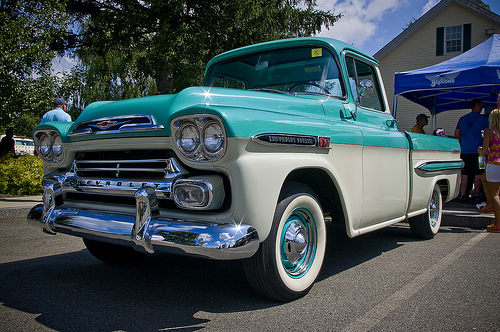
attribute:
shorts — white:
[481, 150, 498, 187]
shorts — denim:
[482, 159, 499, 184]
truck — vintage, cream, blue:
[25, 35, 469, 302]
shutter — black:
[432, 25, 444, 55]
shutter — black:
[462, 20, 472, 52]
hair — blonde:
[486, 108, 497, 131]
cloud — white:
[325, 5, 357, 35]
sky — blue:
[366, 1, 431, 56]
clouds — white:
[313, 4, 430, 46]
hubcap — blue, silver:
[280, 205, 323, 275]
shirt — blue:
[455, 112, 487, 154]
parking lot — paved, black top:
[3, 235, 498, 327]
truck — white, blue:
[44, 25, 485, 302]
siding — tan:
[368, 1, 492, 137]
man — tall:
[450, 95, 487, 210]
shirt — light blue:
[457, 110, 489, 155]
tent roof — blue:
[391, 30, 499, 113]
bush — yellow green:
[3, 161, 31, 193]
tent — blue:
[389, 26, 497, 122]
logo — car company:
[85, 116, 132, 128]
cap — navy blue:
[56, 94, 69, 104]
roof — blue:
[394, 32, 485, 110]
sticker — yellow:
[307, 45, 327, 60]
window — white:
[444, 25, 463, 51]